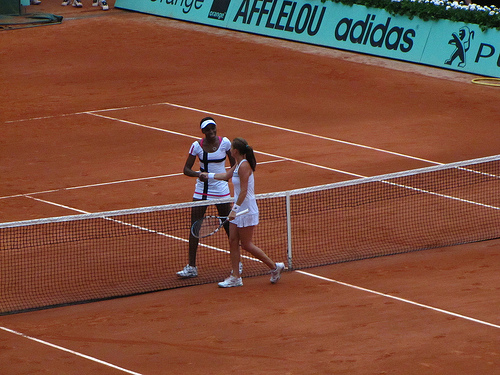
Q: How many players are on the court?
A: Two.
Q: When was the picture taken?
A: Daytime.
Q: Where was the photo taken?
A: At a tennis game.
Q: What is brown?
A: Court.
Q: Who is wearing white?
A: Both players.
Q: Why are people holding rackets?
A: To play tennis.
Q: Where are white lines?
A: On the court.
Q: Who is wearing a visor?
A: Player on left.